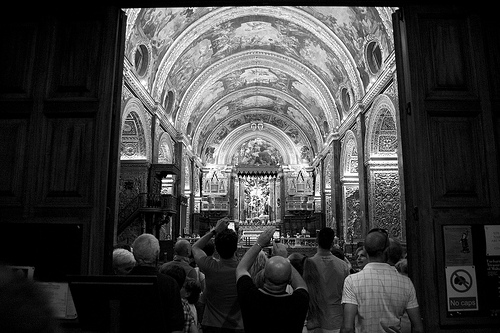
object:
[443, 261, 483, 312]
sign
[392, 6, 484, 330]
wall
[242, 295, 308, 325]
back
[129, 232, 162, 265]
head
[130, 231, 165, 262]
hair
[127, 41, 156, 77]
hole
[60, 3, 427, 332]
doorway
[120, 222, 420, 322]
crowd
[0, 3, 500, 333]
church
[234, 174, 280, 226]
back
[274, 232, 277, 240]
picture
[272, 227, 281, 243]
camera phone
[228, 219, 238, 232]
camera phone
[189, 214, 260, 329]
man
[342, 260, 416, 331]
shirt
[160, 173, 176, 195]
light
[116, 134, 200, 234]
wall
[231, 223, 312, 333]
man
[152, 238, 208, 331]
man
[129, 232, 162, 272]
hair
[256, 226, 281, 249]
hands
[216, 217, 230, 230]
hands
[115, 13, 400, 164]
ceiling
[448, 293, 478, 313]
writing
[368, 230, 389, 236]
glasses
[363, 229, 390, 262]
person's head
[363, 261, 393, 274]
collar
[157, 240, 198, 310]
people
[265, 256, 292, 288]
bald head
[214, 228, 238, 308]
back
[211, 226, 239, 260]
person's head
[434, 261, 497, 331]
hat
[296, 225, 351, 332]
people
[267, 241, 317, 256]
pews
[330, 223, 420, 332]
man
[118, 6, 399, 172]
artwork